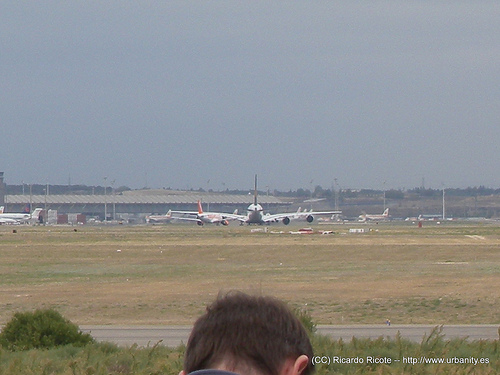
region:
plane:
[189, 200, 324, 231]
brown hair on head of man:
[172, 293, 291, 360]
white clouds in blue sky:
[37, 45, 94, 112]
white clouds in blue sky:
[344, 50, 386, 99]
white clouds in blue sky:
[430, 28, 482, 93]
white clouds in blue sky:
[420, 135, 458, 165]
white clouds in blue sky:
[274, 54, 308, 92]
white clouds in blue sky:
[315, 140, 342, 175]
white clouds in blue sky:
[157, 2, 215, 71]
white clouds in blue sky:
[200, 77, 233, 107]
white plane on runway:
[186, 166, 308, 246]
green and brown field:
[170, 240, 329, 297]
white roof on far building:
[1, 183, 221, 214]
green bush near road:
[13, 286, 93, 369]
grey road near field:
[324, 310, 418, 340]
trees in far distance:
[326, 175, 473, 200]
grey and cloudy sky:
[322, 47, 424, 135]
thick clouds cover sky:
[257, 47, 409, 153]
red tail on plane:
[176, 195, 214, 229]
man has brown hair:
[183, 278, 289, 373]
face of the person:
[171, 268, 326, 372]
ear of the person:
[270, 329, 325, 374]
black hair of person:
[196, 292, 271, 335]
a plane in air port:
[143, 180, 340, 263]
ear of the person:
[281, 344, 313, 372]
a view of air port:
[25, 162, 345, 240]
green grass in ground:
[10, 308, 141, 364]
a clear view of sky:
[26, 13, 494, 174]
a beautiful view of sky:
[13, 15, 481, 162]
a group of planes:
[26, 179, 405, 227]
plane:
[162, 188, 350, 252]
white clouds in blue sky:
[338, 96, 358, 110]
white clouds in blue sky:
[375, 111, 435, 175]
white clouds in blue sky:
[312, 21, 392, 112]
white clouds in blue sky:
[382, 45, 434, 107]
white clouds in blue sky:
[197, 29, 245, 93]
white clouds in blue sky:
[244, 59, 295, 139]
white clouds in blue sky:
[41, 41, 92, 83]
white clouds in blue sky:
[94, 86, 151, 134]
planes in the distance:
[117, 190, 384, 233]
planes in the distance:
[142, 204, 349, 239]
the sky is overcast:
[65, 42, 255, 124]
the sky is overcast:
[131, 30, 275, 145]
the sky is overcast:
[228, 105, 338, 138]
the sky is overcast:
[124, 80, 324, 156]